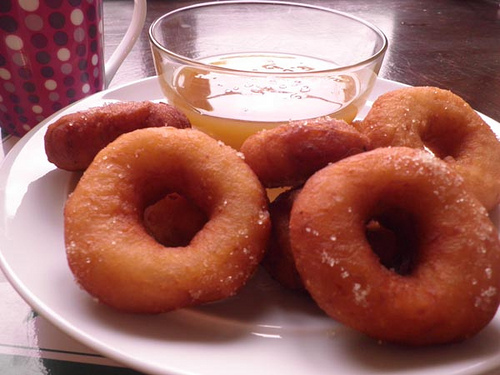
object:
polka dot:
[29, 31, 50, 50]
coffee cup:
[0, 0, 148, 138]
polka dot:
[57, 47, 72, 62]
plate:
[0, 74, 500, 375]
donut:
[63, 125, 273, 316]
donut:
[288, 145, 500, 345]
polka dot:
[11, 52, 29, 67]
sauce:
[171, 51, 360, 153]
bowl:
[147, 0, 389, 153]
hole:
[140, 188, 212, 248]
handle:
[105, 0, 148, 90]